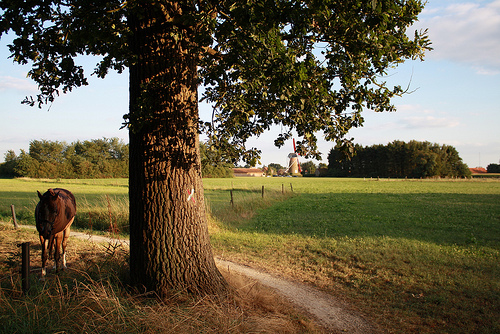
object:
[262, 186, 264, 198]
stick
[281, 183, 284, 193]
stick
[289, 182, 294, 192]
stick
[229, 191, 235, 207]
stick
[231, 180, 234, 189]
stick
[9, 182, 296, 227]
fence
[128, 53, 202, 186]
shadow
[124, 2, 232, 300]
trunk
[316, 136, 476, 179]
trees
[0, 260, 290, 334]
grass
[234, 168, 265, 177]
house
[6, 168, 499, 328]
field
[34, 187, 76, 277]
animal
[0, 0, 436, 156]
leaves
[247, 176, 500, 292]
grass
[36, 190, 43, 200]
ear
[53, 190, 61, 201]
ear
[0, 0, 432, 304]
tree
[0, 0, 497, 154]
sky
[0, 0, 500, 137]
sky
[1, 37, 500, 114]
clouds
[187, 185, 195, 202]
white line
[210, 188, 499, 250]
shade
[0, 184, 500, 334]
ground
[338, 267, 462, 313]
hay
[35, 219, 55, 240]
horse mouth